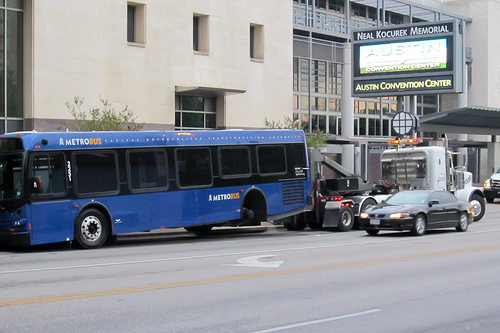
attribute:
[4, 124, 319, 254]
bus — blue, wrecked, big, huge, parked, black, broke, broken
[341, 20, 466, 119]
sign — big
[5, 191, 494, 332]
road — grey, busy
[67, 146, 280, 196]
windows — closed, black, shut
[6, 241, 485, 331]
lines — yellow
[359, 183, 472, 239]
car — black, running, small, moving